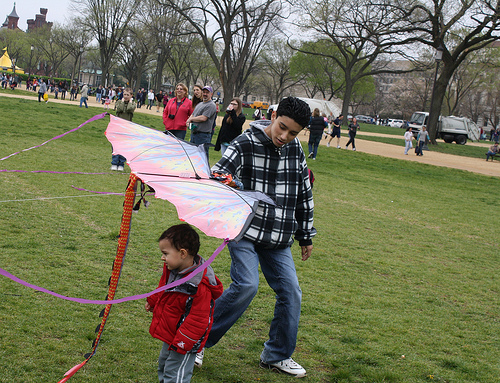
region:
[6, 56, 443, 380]
people in a park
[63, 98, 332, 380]
a boy holding a kite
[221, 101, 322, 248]
a boy in a black and white jacket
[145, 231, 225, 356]
a boy in a red jacket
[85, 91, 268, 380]
a kite over a boy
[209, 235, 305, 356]
a boy wearing blue jeans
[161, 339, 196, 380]
a boy wearing gray and white pants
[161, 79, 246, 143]
people standing in a group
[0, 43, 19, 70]
a yellow tent with a yellow flag on top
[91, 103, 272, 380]
a kite over a little boy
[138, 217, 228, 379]
a kid wears red coat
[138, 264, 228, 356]
red coat has a hood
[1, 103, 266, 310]
kite with purple tails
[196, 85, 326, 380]
boy wears a black squared coat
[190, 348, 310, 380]
a pair of white shoes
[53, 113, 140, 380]
kite has a long orange tail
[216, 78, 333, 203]
boy has black hair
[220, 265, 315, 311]
two knees are bend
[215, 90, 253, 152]
woman drinking from a cup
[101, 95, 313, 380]
Two people playing with a kite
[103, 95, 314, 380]
People playing with a kite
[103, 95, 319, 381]
Two young men playing with a kite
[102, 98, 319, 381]
Two boys playing with a kite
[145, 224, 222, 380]
Young boy wearing a red coat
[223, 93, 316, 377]
Young man wearing a hoodie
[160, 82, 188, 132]
Person wearing a camera around their neck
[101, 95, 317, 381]
Two boys playing with a kite in the grass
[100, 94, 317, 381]
Two young men playing with a kite in the grass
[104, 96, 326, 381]
Two people playing with a kite in the park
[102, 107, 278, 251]
Pink kite on the top of the boy's head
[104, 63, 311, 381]
man holding a kite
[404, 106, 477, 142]
white truck behind the tree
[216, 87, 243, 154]
lady wearing glasses drinking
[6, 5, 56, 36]
brown castle on the hill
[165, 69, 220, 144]
people standing and watching the kites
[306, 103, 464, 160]
many people walking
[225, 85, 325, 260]
man wearing black and white jacket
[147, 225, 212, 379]
little boy wearing red shirt and grey trouser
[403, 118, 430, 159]
couple walking while talking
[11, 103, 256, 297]
This is a kite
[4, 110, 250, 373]
The kite is over a little boy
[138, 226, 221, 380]
The boy is wearing a red jacket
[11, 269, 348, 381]
The people are standing on grass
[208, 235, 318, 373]
The man is wearing blue jeans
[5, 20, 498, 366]
The people are at a park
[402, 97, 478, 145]
A white truck behind a tree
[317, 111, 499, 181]
A walking path made of dirt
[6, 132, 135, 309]
Tails hanging off of the kite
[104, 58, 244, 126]
People watching the kites